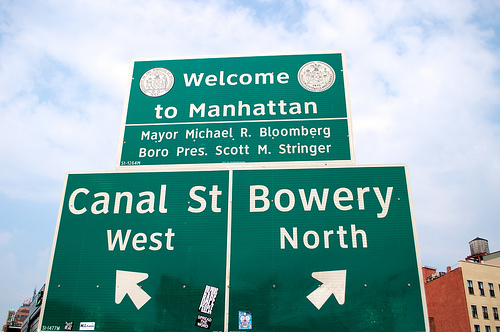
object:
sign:
[118, 53, 352, 164]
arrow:
[111, 268, 153, 309]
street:
[188, 186, 223, 214]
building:
[422, 237, 500, 331]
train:
[19, 285, 48, 331]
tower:
[463, 238, 490, 260]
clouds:
[15, 24, 108, 59]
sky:
[0, 2, 500, 317]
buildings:
[3, 284, 43, 331]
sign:
[47, 163, 229, 332]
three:
[40, 54, 429, 331]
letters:
[276, 72, 291, 84]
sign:
[225, 157, 440, 325]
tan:
[460, 248, 499, 331]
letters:
[172, 131, 179, 139]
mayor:
[140, 131, 179, 143]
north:
[276, 227, 368, 249]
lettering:
[279, 224, 368, 251]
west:
[107, 228, 177, 253]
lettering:
[104, 228, 176, 253]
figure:
[239, 310, 253, 329]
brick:
[425, 265, 470, 331]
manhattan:
[186, 99, 316, 118]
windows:
[470, 281, 474, 294]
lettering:
[140, 131, 179, 143]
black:
[195, 282, 219, 328]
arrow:
[302, 269, 349, 311]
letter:
[183, 72, 205, 87]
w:
[182, 72, 205, 86]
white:
[208, 104, 220, 116]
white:
[259, 127, 267, 137]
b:
[138, 147, 147, 158]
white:
[225, 73, 239, 85]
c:
[226, 73, 238, 86]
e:
[205, 74, 217, 87]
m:
[189, 103, 206, 118]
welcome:
[183, 70, 291, 88]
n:
[222, 104, 235, 117]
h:
[237, 101, 251, 117]